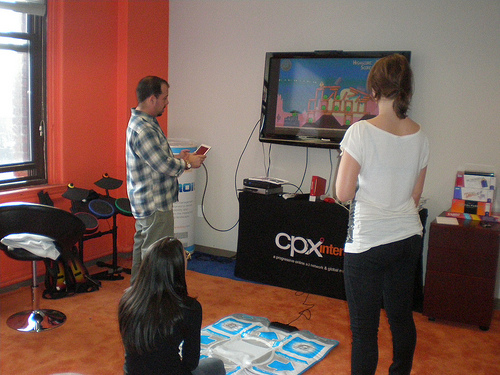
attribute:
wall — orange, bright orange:
[2, 2, 168, 286]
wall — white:
[168, 2, 497, 258]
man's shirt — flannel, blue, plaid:
[125, 114, 187, 212]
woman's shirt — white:
[340, 119, 426, 253]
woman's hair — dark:
[369, 52, 414, 120]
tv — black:
[263, 53, 409, 150]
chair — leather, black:
[1, 204, 85, 331]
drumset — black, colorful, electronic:
[64, 179, 144, 279]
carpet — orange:
[3, 255, 500, 374]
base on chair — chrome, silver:
[2, 261, 66, 329]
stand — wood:
[427, 216, 496, 326]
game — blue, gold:
[195, 315, 323, 373]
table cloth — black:
[238, 192, 420, 296]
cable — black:
[199, 162, 247, 230]